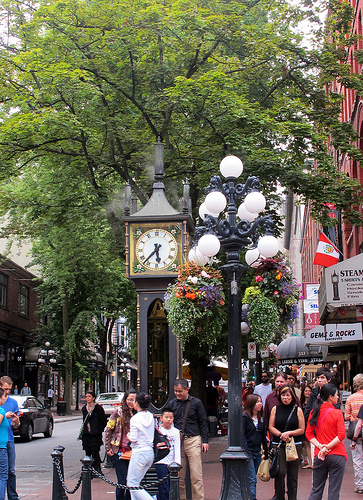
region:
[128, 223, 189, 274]
a clock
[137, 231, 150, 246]
roman numerials on the clock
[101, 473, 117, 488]
a black chain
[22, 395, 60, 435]
a car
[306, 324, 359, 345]
a sign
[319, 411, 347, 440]
women wearing a red shirt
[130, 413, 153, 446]
person wearing a white jacket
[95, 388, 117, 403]
a car on the street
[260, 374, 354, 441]
people standing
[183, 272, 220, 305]
flowers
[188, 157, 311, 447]
white light globes on black pole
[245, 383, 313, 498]
lady in black sleeveless shirt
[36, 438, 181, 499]
black chain and posts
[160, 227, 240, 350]
flower arrangement hanging by lights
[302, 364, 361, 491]
woman wearing red shirt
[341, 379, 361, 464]
orange and white shirt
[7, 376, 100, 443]
black car driving down road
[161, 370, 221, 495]
man wearing khaki pants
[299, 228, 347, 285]
red and white flag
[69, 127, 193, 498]
large clock near road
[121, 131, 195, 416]
Metal clock tower on street.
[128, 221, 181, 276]
Ornate face of clock.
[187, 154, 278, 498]
Ornate light post on street.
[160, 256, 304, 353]
Flowering plants on light pole.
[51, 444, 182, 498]
Barrier with chains on street.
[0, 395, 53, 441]
Black car moving on street.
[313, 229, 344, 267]
Flag on pole hanging from building.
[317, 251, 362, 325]
Awning on building in commercial area.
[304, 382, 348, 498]
Woman in red blouse and grey slacks.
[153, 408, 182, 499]
Boy in white shirt and blue jeans.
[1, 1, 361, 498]
downtown somewhere, where the language is english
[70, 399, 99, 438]
long green+white alpaca hippie bag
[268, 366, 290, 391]
dark hair, centre part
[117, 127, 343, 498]
clock in street matches clock on sign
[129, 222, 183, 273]
it's 5:37pm on the floral cornered clock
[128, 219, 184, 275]
clock lacks second hand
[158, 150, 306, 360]
multicolour floral baskets, white globes amid black iron sea serpent curlicues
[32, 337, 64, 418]
an identical lamppost experience across the street, middle distance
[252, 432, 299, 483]
brown paper bag, black handbag, brown bag in another hand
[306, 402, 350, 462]
red shirt, hot pink strap to nowhere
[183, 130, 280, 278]
Street light with white globes.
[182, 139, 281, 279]
Globes on street light are frosted.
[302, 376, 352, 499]
Woman wearing a red shirt.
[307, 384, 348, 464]
A long sleeve red shirt.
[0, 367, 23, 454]
Two people in blue shirts.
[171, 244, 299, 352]
Hanging flower baskets on street light.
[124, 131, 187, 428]
A clock tower.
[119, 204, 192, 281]
A square clock.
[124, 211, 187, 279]
A clock with roman numerals.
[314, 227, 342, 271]
Red and white flag on building.